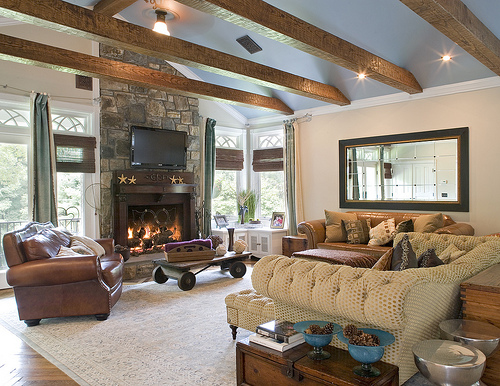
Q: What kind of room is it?
A: It is a living room.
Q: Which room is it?
A: It is a living room.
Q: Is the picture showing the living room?
A: Yes, it is showing the living room.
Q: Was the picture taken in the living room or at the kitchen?
A: It was taken at the living room.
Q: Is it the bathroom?
A: No, it is the living room.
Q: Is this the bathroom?
A: No, it is the living room.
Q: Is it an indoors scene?
A: Yes, it is indoors.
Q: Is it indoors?
A: Yes, it is indoors.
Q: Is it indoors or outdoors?
A: It is indoors.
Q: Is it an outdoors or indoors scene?
A: It is indoors.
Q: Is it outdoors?
A: No, it is indoors.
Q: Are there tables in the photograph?
A: Yes, there is a table.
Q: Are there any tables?
A: Yes, there is a table.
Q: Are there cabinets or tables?
A: Yes, there is a table.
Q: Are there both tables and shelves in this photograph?
A: No, there is a table but no shelves.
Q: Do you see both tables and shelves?
A: No, there is a table but no shelves.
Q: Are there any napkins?
A: No, there are no napkins.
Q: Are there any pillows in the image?
A: Yes, there are pillows.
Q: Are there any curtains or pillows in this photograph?
A: Yes, there are pillows.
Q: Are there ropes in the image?
A: No, there are no ropes.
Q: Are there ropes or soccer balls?
A: No, there are no ropes or soccer balls.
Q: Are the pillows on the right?
A: Yes, the pillows are on the right of the image.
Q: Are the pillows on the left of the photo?
A: No, the pillows are on the right of the image.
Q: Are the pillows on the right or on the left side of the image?
A: The pillows are on the right of the image.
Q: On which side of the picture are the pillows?
A: The pillows are on the right of the image.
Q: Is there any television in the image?
A: Yes, there is a television.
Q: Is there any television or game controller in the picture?
A: Yes, there is a television.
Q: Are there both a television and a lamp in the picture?
A: No, there is a television but no lamps.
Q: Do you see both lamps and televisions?
A: No, there is a television but no lamps.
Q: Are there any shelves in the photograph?
A: No, there are no shelves.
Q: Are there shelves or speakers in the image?
A: No, there are no shelves or speakers.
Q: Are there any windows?
A: Yes, there is a window.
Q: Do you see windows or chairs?
A: Yes, there is a window.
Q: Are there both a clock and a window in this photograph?
A: No, there is a window but no clocks.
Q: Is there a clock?
A: No, there are no clocks.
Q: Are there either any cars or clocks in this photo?
A: No, there are no clocks or cars.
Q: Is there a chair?
A: Yes, there is a chair.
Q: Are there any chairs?
A: Yes, there is a chair.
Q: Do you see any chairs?
A: Yes, there is a chair.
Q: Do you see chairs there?
A: Yes, there is a chair.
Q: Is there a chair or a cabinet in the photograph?
A: Yes, there is a chair.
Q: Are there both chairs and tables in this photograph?
A: Yes, there are both a chair and a table.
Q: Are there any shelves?
A: No, there are no shelves.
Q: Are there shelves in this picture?
A: No, there are no shelves.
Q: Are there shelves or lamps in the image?
A: No, there are no shelves or lamps.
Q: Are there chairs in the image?
A: Yes, there is a chair.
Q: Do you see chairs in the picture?
A: Yes, there is a chair.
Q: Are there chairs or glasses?
A: Yes, there is a chair.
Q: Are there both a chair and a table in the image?
A: Yes, there are both a chair and a table.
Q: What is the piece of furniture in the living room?
A: The piece of furniture is a chair.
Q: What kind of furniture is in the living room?
A: The piece of furniture is a chair.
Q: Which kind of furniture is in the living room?
A: The piece of furniture is a chair.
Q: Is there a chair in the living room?
A: Yes, there is a chair in the living room.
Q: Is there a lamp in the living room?
A: No, there is a chair in the living room.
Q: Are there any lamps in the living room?
A: No, there is a chair in the living room.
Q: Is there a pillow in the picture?
A: Yes, there are pillows.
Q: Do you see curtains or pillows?
A: Yes, there are pillows.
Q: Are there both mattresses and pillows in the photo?
A: No, there are pillows but no mattresses.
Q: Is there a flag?
A: No, there are no flags.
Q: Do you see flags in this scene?
A: No, there are no flags.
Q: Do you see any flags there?
A: No, there are no flags.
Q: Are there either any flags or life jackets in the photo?
A: No, there are no flags or life jackets.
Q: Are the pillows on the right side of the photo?
A: Yes, the pillows are on the right of the image.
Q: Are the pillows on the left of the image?
A: No, the pillows are on the right of the image.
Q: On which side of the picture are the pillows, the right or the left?
A: The pillows are on the right of the image.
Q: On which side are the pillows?
A: The pillows are on the right of the image.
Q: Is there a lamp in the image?
A: No, there are no lamps.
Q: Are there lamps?
A: No, there are no lamps.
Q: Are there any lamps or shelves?
A: No, there are no lamps or shelves.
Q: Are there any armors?
A: No, there are no armors.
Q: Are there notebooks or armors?
A: No, there are no armors or notebooks.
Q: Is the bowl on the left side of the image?
A: No, the bowl is on the right of the image.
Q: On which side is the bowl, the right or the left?
A: The bowl is on the right of the image.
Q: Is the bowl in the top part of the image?
A: No, the bowl is in the bottom of the image.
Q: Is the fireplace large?
A: Yes, the fireplace is large.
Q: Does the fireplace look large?
A: Yes, the fireplace is large.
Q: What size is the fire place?
A: The fire place is large.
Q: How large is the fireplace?
A: The fireplace is large.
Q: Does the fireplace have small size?
A: No, the fireplace is large.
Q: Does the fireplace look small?
A: No, the fireplace is large.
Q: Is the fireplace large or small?
A: The fireplace is large.